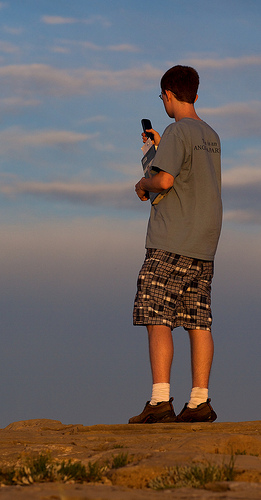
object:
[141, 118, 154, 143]
phone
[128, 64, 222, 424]
boy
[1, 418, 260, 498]
ground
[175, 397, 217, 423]
shoes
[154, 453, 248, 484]
grass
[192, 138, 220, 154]
writing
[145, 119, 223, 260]
shirt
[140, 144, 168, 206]
book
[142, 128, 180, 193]
arm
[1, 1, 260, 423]
sky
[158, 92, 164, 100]
glasses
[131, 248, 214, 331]
shorts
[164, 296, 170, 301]
squares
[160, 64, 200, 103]
hair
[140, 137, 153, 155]
paper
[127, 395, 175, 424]
soles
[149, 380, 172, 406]
sock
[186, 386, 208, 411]
sock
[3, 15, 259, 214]
clouds